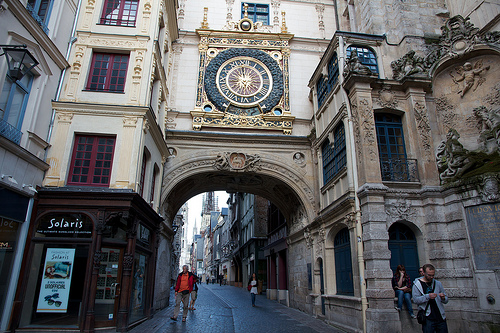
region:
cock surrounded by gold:
[194, 14, 295, 130]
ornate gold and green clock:
[202, 44, 287, 116]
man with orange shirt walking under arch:
[166, 260, 198, 327]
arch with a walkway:
[149, 120, 341, 315]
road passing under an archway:
[141, 250, 331, 331]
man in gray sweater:
[411, 257, 451, 329]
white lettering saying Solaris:
[28, 209, 103, 239]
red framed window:
[61, 125, 122, 190]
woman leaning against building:
[390, 260, 418, 320]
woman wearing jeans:
[389, 261, 417, 324]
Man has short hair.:
[418, 262, 452, 289]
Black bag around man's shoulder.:
[397, 296, 432, 328]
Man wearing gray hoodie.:
[404, 280, 448, 315]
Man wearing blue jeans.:
[421, 314, 450, 329]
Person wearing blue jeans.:
[243, 290, 264, 302]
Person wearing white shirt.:
[246, 278, 260, 292]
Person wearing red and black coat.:
[174, 270, 206, 290]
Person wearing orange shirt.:
[176, 274, 189, 290]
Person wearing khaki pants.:
[167, 289, 200, 318]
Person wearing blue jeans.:
[396, 287, 411, 309]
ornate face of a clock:
[195, 23, 292, 129]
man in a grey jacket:
[410, 256, 450, 328]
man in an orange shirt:
[177, 270, 192, 300]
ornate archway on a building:
[134, 143, 331, 332]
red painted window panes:
[66, 129, 118, 189]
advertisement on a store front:
[25, 203, 102, 328]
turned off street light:
[2, 37, 41, 92]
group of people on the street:
[377, 257, 457, 332]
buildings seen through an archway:
[186, 195, 266, 285]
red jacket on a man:
[171, 269, 195, 296]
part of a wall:
[388, 159, 395, 174]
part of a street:
[263, 320, 270, 330]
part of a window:
[393, 104, 419, 114]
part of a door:
[401, 239, 406, 245]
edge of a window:
[112, 254, 128, 267]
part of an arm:
[251, 268, 254, 291]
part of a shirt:
[416, 283, 425, 293]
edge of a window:
[401, 184, 431, 236]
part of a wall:
[306, 229, 317, 252]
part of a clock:
[236, 123, 258, 155]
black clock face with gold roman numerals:
[205, 52, 282, 111]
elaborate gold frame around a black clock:
[190, 26, 295, 132]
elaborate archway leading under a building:
[154, 138, 323, 318]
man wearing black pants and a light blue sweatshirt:
[409, 261, 452, 330]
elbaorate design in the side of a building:
[389, 13, 497, 180]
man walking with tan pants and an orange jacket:
[173, 262, 193, 324]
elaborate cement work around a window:
[62, 31, 149, 102]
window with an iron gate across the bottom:
[365, 103, 429, 190]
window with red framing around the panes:
[63, 125, 118, 187]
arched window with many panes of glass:
[341, 42, 382, 75]